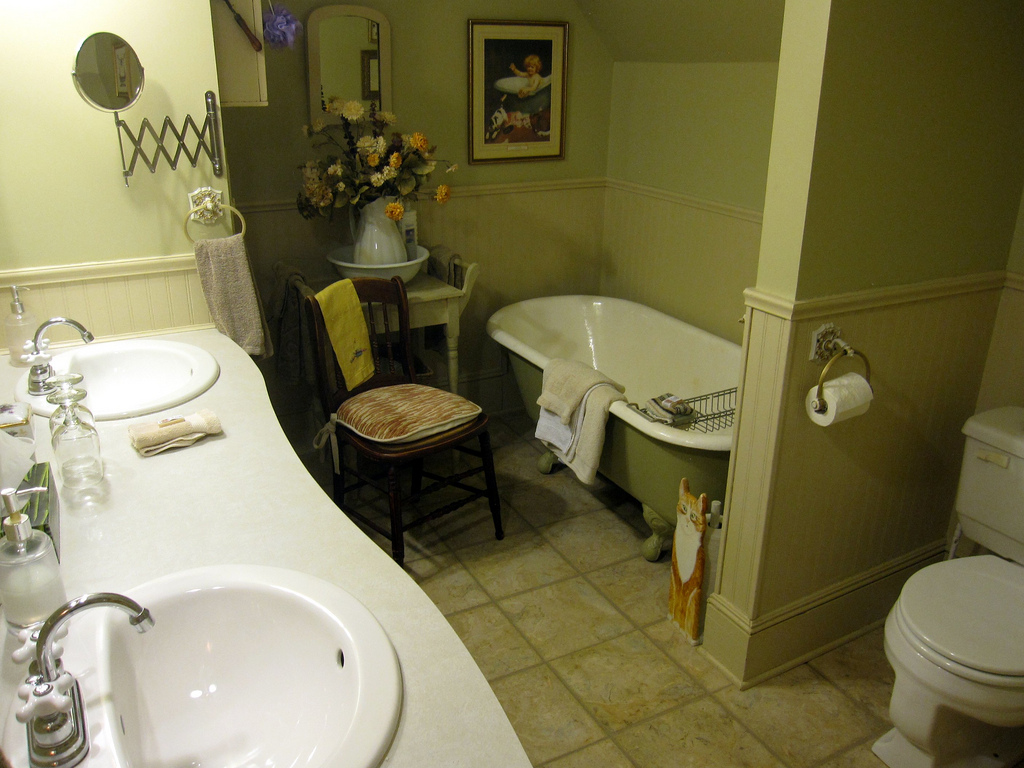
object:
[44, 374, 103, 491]
glasses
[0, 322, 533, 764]
sink counter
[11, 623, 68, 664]
right knob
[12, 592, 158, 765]
faucet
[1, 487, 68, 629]
soap dispenser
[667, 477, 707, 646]
cat decor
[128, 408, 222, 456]
towel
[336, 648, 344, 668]
drain hole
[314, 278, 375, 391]
towel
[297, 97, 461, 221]
flowers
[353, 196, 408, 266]
vase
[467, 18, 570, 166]
art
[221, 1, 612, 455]
wall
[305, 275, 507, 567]
chair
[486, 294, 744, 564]
bath tub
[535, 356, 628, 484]
towel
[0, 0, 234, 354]
wall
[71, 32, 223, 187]
mirror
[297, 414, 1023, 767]
floor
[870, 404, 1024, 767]
toilet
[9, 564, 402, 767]
sink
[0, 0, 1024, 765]
bathroom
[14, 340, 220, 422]
sink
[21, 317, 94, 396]
faucet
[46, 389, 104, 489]
drinking glass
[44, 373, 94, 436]
drinking glass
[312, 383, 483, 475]
pad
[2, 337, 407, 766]
sinks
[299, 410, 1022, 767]
tiles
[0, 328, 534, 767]
counter top